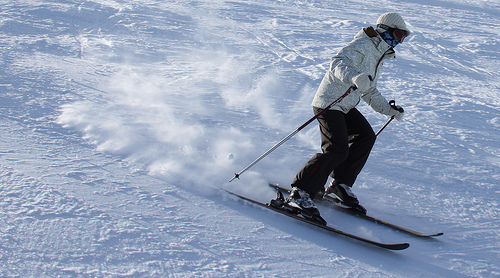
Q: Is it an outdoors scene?
A: Yes, it is outdoors.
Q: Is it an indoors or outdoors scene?
A: It is outdoors.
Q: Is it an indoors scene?
A: No, it is outdoors.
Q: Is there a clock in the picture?
A: No, there are no clocks.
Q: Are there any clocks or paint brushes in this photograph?
A: No, there are no clocks or paint brushes.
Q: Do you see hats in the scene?
A: Yes, there is a hat.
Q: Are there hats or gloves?
A: Yes, there is a hat.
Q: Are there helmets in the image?
A: No, there are no helmets.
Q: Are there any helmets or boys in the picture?
A: No, there are no helmets or boys.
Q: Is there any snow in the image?
A: Yes, there is snow.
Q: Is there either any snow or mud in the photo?
A: Yes, there is snow.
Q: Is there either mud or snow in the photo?
A: Yes, there is snow.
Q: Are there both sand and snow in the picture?
A: No, there is snow but no sand.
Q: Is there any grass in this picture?
A: No, there is no grass.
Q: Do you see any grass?
A: No, there is no grass.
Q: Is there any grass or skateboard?
A: No, there are no grass or skateboards.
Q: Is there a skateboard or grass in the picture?
A: No, there are no grass or skateboards.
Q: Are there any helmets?
A: No, there are no helmets.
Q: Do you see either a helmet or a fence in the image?
A: No, there are no helmets or fences.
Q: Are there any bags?
A: No, there are no bags.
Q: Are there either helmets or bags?
A: No, there are no bags or helmets.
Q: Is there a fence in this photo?
A: No, there are no fences.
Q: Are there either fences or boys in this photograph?
A: No, there are no fences or boys.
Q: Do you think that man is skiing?
A: Yes, the man is skiing.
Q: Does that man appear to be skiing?
A: Yes, the man is skiing.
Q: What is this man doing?
A: The man is skiing.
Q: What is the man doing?
A: The man is skiing.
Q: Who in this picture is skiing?
A: The man is skiing.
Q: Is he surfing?
A: No, the man is skiing.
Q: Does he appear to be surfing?
A: No, the man is skiing.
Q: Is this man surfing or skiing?
A: The man is skiing.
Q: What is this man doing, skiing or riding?
A: The man is skiing.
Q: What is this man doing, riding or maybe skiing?
A: The man is skiing.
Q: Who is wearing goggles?
A: The man is wearing goggles.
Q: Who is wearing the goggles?
A: The man is wearing goggles.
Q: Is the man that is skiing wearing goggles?
A: Yes, the man is wearing goggles.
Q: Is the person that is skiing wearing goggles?
A: Yes, the man is wearing goggles.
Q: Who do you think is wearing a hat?
A: The man is wearing a hat.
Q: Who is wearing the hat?
A: The man is wearing a hat.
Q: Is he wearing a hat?
A: Yes, the man is wearing a hat.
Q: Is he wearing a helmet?
A: No, the man is wearing a hat.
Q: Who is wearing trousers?
A: The man is wearing trousers.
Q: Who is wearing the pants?
A: The man is wearing trousers.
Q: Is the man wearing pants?
A: Yes, the man is wearing pants.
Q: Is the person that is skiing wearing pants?
A: Yes, the man is wearing pants.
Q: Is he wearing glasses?
A: No, the man is wearing pants.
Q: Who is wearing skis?
A: The man is wearing skis.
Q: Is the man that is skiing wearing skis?
A: Yes, the man is wearing skis.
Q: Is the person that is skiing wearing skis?
A: Yes, the man is wearing skis.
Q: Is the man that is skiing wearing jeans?
A: No, the man is wearing skis.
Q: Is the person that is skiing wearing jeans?
A: No, the man is wearing skis.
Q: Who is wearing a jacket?
A: The man is wearing a jacket.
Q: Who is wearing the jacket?
A: The man is wearing a jacket.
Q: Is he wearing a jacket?
A: Yes, the man is wearing a jacket.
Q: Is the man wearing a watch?
A: No, the man is wearing a jacket.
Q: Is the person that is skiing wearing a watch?
A: No, the man is wearing a jacket.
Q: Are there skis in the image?
A: Yes, there are skis.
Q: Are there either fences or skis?
A: Yes, there are skis.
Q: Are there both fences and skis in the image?
A: No, there are skis but no fences.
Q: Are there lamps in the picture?
A: No, there are no lamps.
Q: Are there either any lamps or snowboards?
A: No, there are no lamps or snowboards.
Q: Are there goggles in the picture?
A: Yes, there are goggles.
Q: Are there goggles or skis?
A: Yes, there are goggles.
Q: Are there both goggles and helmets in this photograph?
A: No, there are goggles but no helmets.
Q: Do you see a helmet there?
A: No, there are no helmets.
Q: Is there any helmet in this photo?
A: No, there are no helmets.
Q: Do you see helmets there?
A: No, there are no helmets.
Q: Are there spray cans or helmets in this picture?
A: No, there are no helmets or spray cans.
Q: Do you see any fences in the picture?
A: No, there are no fences.